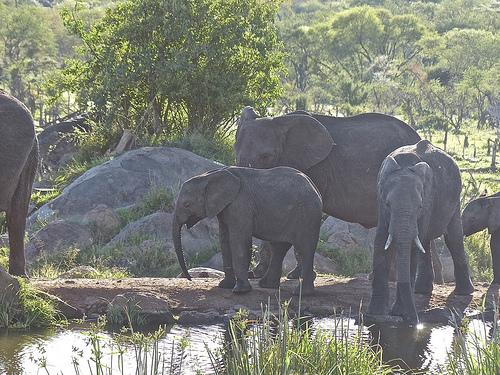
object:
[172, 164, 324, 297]
elephant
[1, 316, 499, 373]
water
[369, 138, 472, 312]
elephant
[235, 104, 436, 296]
elephant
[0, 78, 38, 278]
elephant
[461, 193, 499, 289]
elephant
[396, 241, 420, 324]
trunk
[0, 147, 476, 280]
boulders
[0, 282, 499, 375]
plants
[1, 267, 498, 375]
foreground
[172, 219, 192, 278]
trunk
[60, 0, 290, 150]
tree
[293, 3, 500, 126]
trees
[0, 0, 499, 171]
distance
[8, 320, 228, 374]
sunlight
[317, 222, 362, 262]
rock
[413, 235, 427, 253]
husk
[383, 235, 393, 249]
husk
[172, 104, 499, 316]
elephants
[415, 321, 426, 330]
sun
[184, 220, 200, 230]
mouth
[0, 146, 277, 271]
boulder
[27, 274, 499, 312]
path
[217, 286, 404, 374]
grass